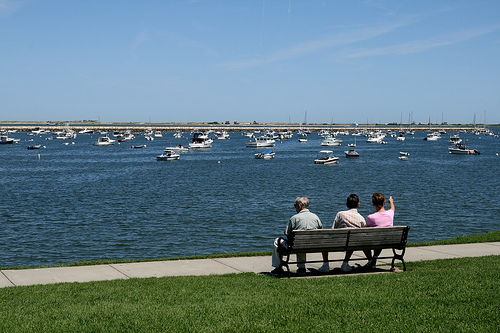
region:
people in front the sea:
[263, 173, 420, 275]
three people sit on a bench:
[269, 184, 419, 276]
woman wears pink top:
[359, 187, 401, 232]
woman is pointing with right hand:
[364, 182, 402, 232]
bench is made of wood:
[276, 222, 418, 284]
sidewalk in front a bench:
[7, 241, 498, 293]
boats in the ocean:
[3, 125, 496, 175]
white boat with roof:
[311, 140, 344, 171]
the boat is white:
[367, 128, 388, 144]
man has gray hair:
[281, 187, 325, 234]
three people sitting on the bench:
[266, 175, 421, 277]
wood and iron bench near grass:
[261, 193, 421, 293]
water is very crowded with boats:
[7, 113, 496, 178]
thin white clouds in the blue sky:
[198, 31, 445, 85]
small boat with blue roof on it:
[253, 140, 278, 163]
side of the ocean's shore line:
[41, 115, 192, 135]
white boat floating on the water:
[86, 132, 120, 150]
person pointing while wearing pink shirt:
[366, 181, 413, 253]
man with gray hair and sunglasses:
[290, 193, 312, 216]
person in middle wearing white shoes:
[316, 259, 354, 277]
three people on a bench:
[256, 190, 413, 279]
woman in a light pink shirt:
[363, 192, 405, 229]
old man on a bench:
[261, 189, 335, 280]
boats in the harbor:
[1, 98, 498, 179]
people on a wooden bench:
[251, 187, 419, 289]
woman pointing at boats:
[363, 184, 402, 240]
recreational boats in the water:
[1, 102, 498, 189]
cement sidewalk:
[0, 239, 499, 302]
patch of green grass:
[0, 251, 497, 331]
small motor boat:
[444, 142, 486, 163]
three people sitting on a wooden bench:
[270, 191, 407, 278]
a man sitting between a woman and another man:
[318, 192, 367, 273]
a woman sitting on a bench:
[365, 191, 395, 270]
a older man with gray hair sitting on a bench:
[271, 195, 322, 275]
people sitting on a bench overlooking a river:
[269, 190, 409, 276]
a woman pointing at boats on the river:
[360, 190, 396, 272]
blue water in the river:
[0, 166, 204, 251]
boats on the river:
[0, 129, 499, 166]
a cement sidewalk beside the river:
[0, 249, 270, 289]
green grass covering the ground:
[126, 279, 281, 331]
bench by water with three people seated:
[256, 179, 418, 278]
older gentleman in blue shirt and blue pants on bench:
[270, 193, 327, 283]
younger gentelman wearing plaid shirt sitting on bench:
[317, 191, 369, 271]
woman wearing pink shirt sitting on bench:
[357, 186, 400, 269]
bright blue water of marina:
[3, 128, 495, 268]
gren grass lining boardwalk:
[1, 264, 498, 326]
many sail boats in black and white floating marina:
[4, 104, 494, 176]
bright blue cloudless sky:
[5, 0, 498, 121]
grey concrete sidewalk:
[2, 245, 499, 287]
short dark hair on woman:
[369, 191, 389, 208]